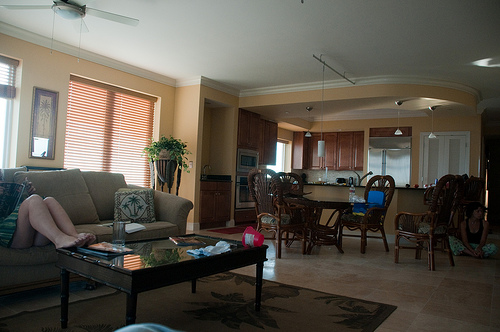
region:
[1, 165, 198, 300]
A LIVING ROOM SOFA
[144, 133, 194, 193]
A PLANT IN A PLANT STAND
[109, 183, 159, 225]
A COUCH THROW PILLOW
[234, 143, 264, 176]
A WHITE MICROWAVE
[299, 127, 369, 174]
BROWN WOODEN KITCHEN CABINETS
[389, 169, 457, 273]
A BROWN WOODEN CHAIR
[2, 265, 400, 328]
A LIVING ROOM AREA RUG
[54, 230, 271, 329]
A WOODEN AND GLASS COFFEE TABLE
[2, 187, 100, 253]
SOMEONE SITTING ON THE COUCH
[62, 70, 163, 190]
WINDOW BLINDS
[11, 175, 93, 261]
a persons feet on the table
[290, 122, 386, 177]
the cabinets are brown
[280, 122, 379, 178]
the cabinets are made of wood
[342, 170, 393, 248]
a baby seat in the chair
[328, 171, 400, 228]
the baby seat is blue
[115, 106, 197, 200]
a plant by the window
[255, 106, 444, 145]
the lights are off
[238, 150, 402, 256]
chairs at the table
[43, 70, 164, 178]
the blinds are closed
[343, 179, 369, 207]
a water bottle on the table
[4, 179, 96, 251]
a person on couch with their feet up on a table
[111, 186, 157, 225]
throw pillow with palm trees design on it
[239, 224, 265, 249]
red object on a table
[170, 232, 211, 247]
booklet on a table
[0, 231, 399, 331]
wooden table on a large area rug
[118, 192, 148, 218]
palm tree design on a pillow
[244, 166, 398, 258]
wooden chairs around a table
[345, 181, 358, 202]
bottle of water on a wooden dining room table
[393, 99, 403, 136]
light hanginf from a kitchen's ceiling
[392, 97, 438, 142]
two lights hanging from a kitchen's ceiling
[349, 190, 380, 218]
blue child's high chair in wicker chair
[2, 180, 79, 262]
person sitting on couch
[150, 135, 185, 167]
potted plant next to window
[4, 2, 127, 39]
ceiling fan with white blades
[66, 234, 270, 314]
coffee table in front of couch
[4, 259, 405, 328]
area rug under coffee table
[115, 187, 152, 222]
throw pillow on couch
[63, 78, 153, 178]
blinds covering windows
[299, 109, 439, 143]
three drop lights in kitchen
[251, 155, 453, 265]
table and four chairs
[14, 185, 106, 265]
bent legs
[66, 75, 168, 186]
wooden blinds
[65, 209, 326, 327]
coffee table with magazines on it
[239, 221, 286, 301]
red bucket on table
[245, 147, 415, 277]
three chairs at table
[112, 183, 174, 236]
pillow with palm trees on sofa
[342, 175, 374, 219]
plastic water bottle on table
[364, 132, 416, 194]
stainless steel refrigerator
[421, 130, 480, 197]
with door with two panels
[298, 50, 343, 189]
white light fixture hanging from ceiling